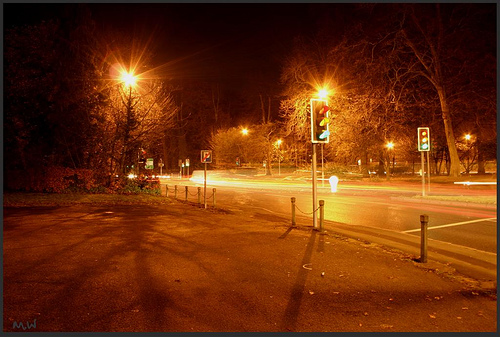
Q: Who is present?
A: Nobody.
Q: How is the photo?
A: Clear.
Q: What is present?
A: Trees.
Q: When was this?
A: Nighttime.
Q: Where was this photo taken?
A: On city street.